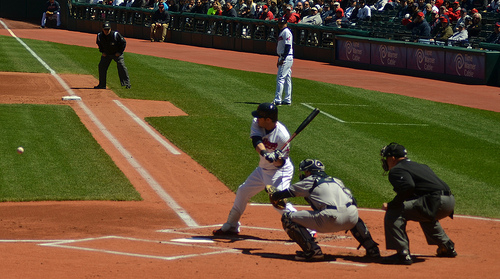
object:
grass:
[1, 108, 123, 202]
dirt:
[7, 97, 31, 103]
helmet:
[248, 102, 280, 122]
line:
[1, 20, 199, 228]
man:
[270, 18, 294, 106]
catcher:
[266, 157, 382, 260]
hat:
[101, 20, 112, 31]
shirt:
[275, 27, 296, 55]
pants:
[276, 54, 295, 104]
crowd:
[73, 0, 499, 49]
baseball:
[17, 146, 25, 154]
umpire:
[380, 142, 457, 265]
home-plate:
[168, 236, 222, 244]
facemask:
[378, 143, 389, 175]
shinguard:
[280, 211, 313, 259]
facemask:
[297, 159, 308, 183]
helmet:
[298, 158, 326, 179]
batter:
[211, 101, 294, 236]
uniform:
[284, 174, 376, 252]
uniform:
[276, 26, 294, 103]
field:
[1, 18, 497, 278]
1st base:
[61, 94, 82, 103]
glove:
[263, 183, 287, 211]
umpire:
[96, 20, 133, 88]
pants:
[384, 191, 455, 250]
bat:
[282, 106, 321, 150]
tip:
[297, 105, 322, 134]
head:
[254, 103, 280, 132]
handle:
[278, 132, 295, 152]